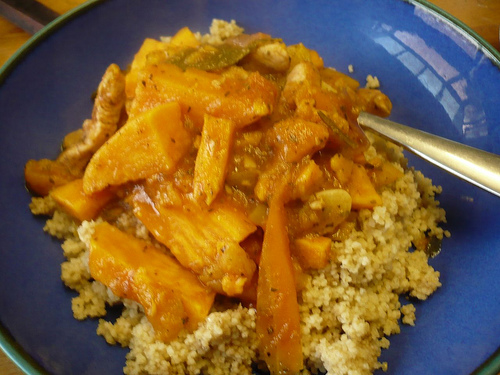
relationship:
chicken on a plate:
[24, 23, 390, 375] [444, 316, 480, 359]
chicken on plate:
[24, 23, 390, 375] [48, 13, 490, 345]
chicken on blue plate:
[24, 23, 390, 375] [1, 0, 500, 375]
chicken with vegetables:
[24, 23, 390, 375] [35, 8, 453, 346]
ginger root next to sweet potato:
[57, 64, 124, 179] [25, 157, 81, 195]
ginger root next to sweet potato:
[57, 64, 124, 179] [49, 176, 114, 221]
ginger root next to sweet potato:
[57, 64, 124, 179] [82, 102, 191, 197]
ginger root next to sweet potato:
[57, 64, 124, 179] [125, 62, 277, 131]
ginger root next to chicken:
[57, 64, 124, 179] [24, 23, 390, 375]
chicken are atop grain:
[24, 23, 390, 375] [327, 228, 440, 373]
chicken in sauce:
[24, 23, 390, 375] [192, 114, 275, 192]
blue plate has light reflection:
[1, 0, 500, 375] [373, 11, 490, 142]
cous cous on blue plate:
[27, 15, 435, 373] [1, 0, 498, 373]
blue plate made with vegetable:
[1, 0, 500, 375] [77, 223, 217, 328]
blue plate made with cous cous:
[1, 0, 500, 375] [27, 201, 462, 363]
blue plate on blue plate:
[1, 0, 500, 375] [1, 0, 500, 375]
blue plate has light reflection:
[1, 0, 500, 375] [327, 11, 490, 143]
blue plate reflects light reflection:
[1, 0, 500, 375] [373, 11, 490, 142]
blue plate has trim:
[1, 0, 500, 375] [393, 4, 497, 74]